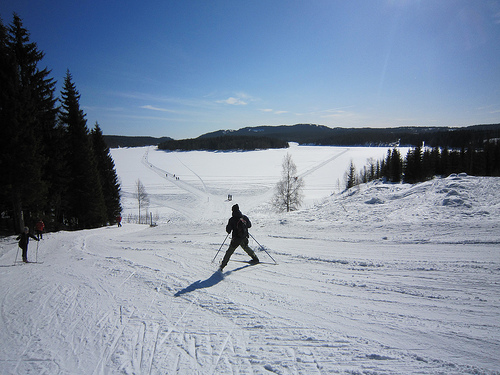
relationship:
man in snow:
[206, 185, 257, 297] [76, 278, 493, 356]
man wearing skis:
[206, 185, 257, 297] [228, 261, 294, 268]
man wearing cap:
[216, 203, 260, 268] [232, 202, 249, 211]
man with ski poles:
[216, 203, 260, 268] [12, 244, 53, 267]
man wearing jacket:
[216, 203, 260, 268] [230, 217, 252, 229]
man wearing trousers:
[206, 185, 257, 297] [231, 238, 256, 263]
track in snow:
[279, 242, 479, 302] [76, 278, 493, 356]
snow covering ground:
[76, 278, 493, 356] [62, 258, 442, 366]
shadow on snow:
[188, 262, 245, 312] [76, 278, 493, 356]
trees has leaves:
[18, 85, 120, 236] [78, 160, 103, 196]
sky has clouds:
[54, 8, 436, 127] [131, 87, 310, 119]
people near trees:
[149, 161, 204, 200] [18, 85, 120, 236]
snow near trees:
[76, 278, 493, 356] [18, 85, 120, 236]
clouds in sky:
[131, 87, 310, 119] [54, 8, 436, 127]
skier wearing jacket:
[31, 212, 50, 249] [35, 222, 48, 231]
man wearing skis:
[216, 203, 260, 268] [228, 261, 294, 268]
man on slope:
[216, 203, 260, 268] [183, 246, 490, 342]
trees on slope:
[18, 85, 120, 236] [183, 246, 490, 342]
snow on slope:
[76, 278, 493, 356] [183, 246, 490, 342]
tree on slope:
[275, 138, 324, 223] [183, 246, 490, 342]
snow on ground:
[76, 278, 493, 356] [62, 258, 442, 366]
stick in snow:
[206, 243, 220, 262] [76, 278, 493, 356]